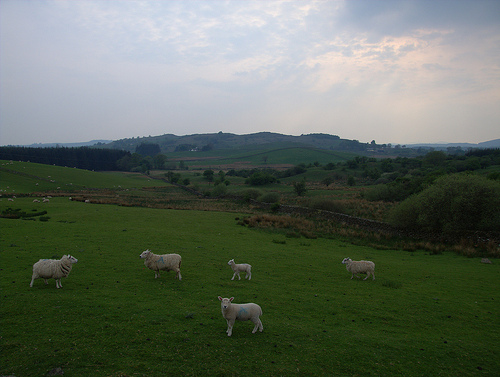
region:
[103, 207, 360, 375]
sheep in a field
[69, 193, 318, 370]
sheep walkig in a field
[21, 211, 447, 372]
sheep standing in a field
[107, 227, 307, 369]
a field of grass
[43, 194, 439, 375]
a field of green grass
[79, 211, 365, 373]
a green grass field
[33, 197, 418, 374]
a field with sheep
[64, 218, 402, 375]
a field with standing sheep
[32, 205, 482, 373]
a field with walking sheep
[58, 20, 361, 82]
a blue sky with clouds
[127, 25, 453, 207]
the sky is cloudy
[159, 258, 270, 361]
the sheep are in the pasture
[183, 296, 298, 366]
the sheep is standing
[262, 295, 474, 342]
the sheep is on the grass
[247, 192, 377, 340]
a bush is by the sheep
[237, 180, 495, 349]
a bush is by a fence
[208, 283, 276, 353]
the sheep is marked withe blue paint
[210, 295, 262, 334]
the sheep is looking at the camera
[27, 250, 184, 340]
the sheep is looking at the other sheep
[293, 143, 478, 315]
the trees are in the distance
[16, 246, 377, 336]
There are five sheep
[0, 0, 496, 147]
The sky is cloudy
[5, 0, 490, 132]
The sun brightens the sky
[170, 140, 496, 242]
There are trees on the hillside.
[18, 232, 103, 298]
this sheep is looking right.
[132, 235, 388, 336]
These sheep are looking left.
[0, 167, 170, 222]
These sheep are far away.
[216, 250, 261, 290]
This sheep is a baby.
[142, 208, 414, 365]
sheep in a field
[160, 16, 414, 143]
a sky that is blue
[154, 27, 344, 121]
a sky with clouds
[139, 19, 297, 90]
a blue sky with clouds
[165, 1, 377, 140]
a sky with white clouds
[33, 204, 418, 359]
a field with sheep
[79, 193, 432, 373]
a field with walking sheep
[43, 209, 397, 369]
walking sheep in a field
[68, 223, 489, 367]
a field of green grass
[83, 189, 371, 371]
sheep on the grass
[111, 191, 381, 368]
sheep walking on the grass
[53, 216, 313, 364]
walking sheep in a field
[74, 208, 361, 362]
a field of green grass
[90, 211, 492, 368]
a field of short green grass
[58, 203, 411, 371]
sheep in a field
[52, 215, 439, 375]
sheep walkin gon the grass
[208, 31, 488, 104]
a sky with clouds